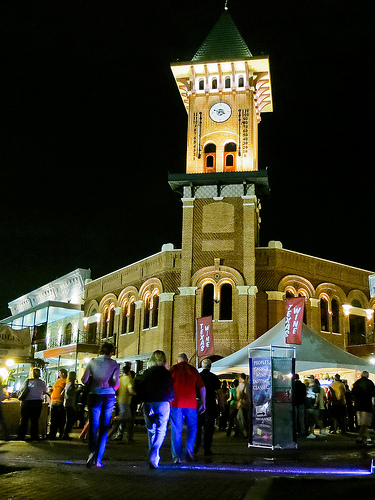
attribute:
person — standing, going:
[80, 336, 122, 475]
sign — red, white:
[279, 295, 305, 347]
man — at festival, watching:
[167, 353, 206, 467]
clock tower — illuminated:
[166, 3, 261, 248]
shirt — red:
[168, 364, 203, 410]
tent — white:
[198, 310, 374, 383]